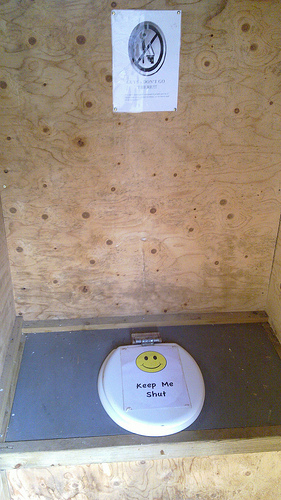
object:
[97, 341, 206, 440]
lid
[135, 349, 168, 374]
face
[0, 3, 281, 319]
wall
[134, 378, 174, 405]
keep me shut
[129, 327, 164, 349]
twist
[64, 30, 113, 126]
cricles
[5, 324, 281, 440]
seat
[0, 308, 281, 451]
frame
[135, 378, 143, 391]
letter k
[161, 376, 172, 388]
letter m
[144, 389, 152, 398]
letter s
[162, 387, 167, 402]
letter t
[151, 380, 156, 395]
letter p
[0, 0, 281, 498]
outhouse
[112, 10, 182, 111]
sign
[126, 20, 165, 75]
what is not allowed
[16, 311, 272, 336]
wooden strips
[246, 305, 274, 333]
corner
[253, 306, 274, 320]
tacks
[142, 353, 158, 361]
black eyes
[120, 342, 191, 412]
sign